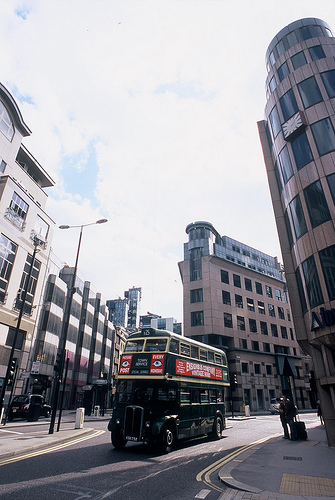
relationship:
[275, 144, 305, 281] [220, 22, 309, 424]
wall of building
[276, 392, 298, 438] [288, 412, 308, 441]
man has suitcase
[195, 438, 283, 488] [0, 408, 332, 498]
yellow lines on road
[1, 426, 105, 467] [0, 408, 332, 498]
yellow lines on road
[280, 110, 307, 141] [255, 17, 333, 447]
clock on building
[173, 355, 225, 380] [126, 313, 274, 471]
sign on bus